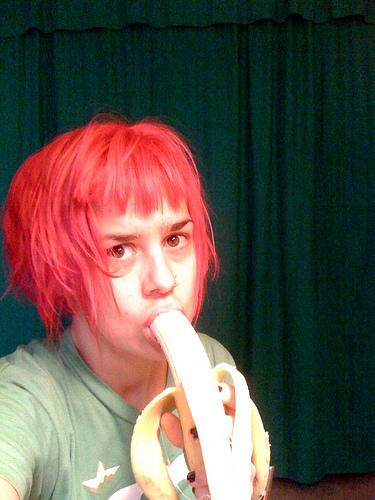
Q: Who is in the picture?
A: A woman.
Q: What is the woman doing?
A: Eating.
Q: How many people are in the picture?
A: 1.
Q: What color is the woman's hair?
A: Red.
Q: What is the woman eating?
A: A banana.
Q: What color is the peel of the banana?
A: Yellow.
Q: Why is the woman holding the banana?
A: To eat.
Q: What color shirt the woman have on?
A: Its green.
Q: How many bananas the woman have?
A: Only one.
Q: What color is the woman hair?
A: Fire red.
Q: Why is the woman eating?
A: Hungry.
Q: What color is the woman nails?
A: Black.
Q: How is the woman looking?
A: Tired.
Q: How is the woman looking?
A: Very tired.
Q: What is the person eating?
A: Banana.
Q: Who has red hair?
A: The person.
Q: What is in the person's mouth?
A: A banana.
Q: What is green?
A: Curtain.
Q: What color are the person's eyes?
A: Brown.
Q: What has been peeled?
A: The banana.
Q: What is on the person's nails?
A: Nail Polish.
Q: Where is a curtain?
A: Behind the person.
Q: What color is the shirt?
A: Green.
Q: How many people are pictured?
A: One.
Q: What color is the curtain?
A: Green.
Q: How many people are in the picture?
A: One.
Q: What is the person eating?
A: A banana.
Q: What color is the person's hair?
A: Red.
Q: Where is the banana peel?
A: On the banana.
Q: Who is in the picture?
A: A woman.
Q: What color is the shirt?
A: Green.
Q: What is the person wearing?
A: T-shirt.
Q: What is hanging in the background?
A: Curtains.